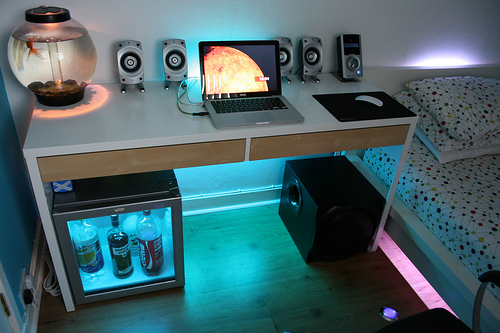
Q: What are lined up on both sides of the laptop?
A: Speakers.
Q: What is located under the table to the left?
A: Small refrigerator.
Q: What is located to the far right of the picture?
A: Bed.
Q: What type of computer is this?
A: Laptop.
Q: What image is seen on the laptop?
A: Planet.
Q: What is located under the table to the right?
A: Sub-woofer.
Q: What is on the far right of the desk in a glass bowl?
A: Gold fish.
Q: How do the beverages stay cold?
A: Mini fridge.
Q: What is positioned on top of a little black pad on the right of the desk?
A: Computer mouse.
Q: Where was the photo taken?
A: In a bedroom.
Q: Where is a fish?
A: In a fishbowl.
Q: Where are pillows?
A: On the bed.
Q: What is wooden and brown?
A: The floor.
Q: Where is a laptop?
A: On the desk.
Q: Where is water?
A: In the fishbowl.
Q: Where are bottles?
A: In mini fridge.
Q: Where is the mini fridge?
A: Under the desk.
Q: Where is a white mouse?
A: On mouse pad.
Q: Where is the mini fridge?
A: Under the desk on the left.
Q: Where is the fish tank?
A: On top of the white desk.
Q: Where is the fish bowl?
A: On the table.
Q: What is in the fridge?
A: Beverages.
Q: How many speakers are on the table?
A: Five.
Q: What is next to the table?
A: A bed.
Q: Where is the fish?
A: In the fishbowl.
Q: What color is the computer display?
A: Orange.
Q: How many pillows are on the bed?
A: Three.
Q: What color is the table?
A: White.